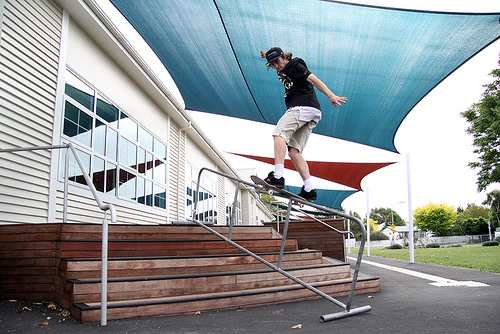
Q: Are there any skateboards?
A: Yes, there is a skateboard.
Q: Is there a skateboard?
A: Yes, there is a skateboard.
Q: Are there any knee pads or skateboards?
A: Yes, there is a skateboard.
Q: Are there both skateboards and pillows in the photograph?
A: No, there is a skateboard but no pillows.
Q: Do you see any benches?
A: No, there are no benches.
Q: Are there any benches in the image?
A: No, there are no benches.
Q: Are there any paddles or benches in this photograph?
A: No, there are no benches or paddles.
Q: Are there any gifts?
A: No, there are no gifts.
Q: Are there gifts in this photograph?
A: No, there are no gifts.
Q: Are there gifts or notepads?
A: No, there are no gifts or notepads.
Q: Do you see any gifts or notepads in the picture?
A: No, there are no gifts or notepads.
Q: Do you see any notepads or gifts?
A: No, there are no gifts or notepads.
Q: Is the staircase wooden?
A: Yes, the staircase is wooden.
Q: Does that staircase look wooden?
A: Yes, the staircase is wooden.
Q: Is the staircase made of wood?
A: Yes, the staircase is made of wood.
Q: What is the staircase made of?
A: The staircase is made of wood.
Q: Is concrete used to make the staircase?
A: No, the staircase is made of wood.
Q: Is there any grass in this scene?
A: Yes, there is grass.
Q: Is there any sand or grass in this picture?
A: Yes, there is grass.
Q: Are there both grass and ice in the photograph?
A: No, there is grass but no ice.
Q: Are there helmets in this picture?
A: No, there are no helmets.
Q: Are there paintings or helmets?
A: No, there are no helmets or paintings.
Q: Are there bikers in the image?
A: No, there are no bikers.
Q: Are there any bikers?
A: No, there are no bikers.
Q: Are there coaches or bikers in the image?
A: No, there are no bikers or coaches.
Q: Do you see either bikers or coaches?
A: No, there are no bikers or coaches.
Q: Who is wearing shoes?
A: The man is wearing shoes.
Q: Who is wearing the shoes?
A: The man is wearing shoes.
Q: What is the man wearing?
A: The man is wearing shoes.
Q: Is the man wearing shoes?
A: Yes, the man is wearing shoes.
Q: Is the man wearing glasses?
A: No, the man is wearing shoes.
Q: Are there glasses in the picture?
A: No, there are no glasses.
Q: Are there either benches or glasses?
A: No, there are no glasses or benches.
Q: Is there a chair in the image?
A: No, there are no chairs.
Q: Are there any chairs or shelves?
A: No, there are no chairs or shelves.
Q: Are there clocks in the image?
A: No, there are no clocks.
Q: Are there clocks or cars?
A: No, there are no clocks or cars.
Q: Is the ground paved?
A: Yes, the ground is paved.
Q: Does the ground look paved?
A: Yes, the ground is paved.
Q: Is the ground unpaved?
A: No, the ground is paved.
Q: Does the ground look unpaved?
A: No, the ground is paved.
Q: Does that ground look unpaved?
A: No, the ground is paved.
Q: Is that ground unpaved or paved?
A: The ground is paved.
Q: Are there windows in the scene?
A: Yes, there is a window.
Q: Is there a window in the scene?
A: Yes, there is a window.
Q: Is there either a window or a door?
A: Yes, there is a window.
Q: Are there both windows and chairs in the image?
A: No, there is a window but no chairs.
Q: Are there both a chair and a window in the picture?
A: No, there is a window but no chairs.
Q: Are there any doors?
A: No, there are no doors.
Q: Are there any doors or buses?
A: No, there are no doors or buses.